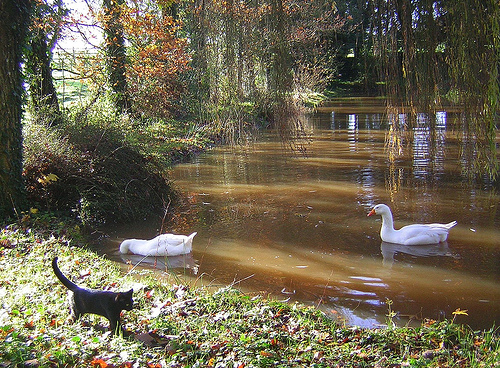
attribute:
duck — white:
[360, 194, 467, 258]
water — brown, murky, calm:
[282, 153, 369, 203]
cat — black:
[47, 259, 151, 338]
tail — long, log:
[45, 248, 77, 292]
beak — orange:
[367, 207, 377, 216]